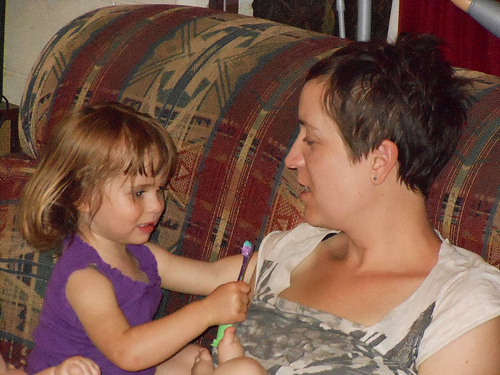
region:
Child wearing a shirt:
[18, 231, 168, 373]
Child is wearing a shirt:
[22, 235, 169, 373]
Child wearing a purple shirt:
[22, 230, 162, 372]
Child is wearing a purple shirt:
[20, 232, 163, 374]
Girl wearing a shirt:
[21, 235, 168, 371]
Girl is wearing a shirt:
[23, 230, 166, 371]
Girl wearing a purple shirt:
[20, 228, 167, 373]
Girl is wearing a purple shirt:
[20, 232, 164, 373]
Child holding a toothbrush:
[207, 239, 258, 363]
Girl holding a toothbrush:
[207, 238, 254, 363]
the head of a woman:
[276, 52, 441, 268]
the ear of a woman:
[339, 130, 424, 180]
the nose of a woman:
[275, 134, 335, 170]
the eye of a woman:
[294, 110, 352, 163]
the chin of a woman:
[288, 177, 355, 237]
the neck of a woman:
[295, 191, 434, 315]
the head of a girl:
[56, 108, 205, 261]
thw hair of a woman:
[284, 42, 464, 179]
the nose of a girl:
[146, 180, 198, 220]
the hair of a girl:
[18, 79, 212, 239]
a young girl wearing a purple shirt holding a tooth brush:
[16, 73, 268, 373]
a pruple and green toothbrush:
[208, 235, 271, 363]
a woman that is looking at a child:
[193, 36, 490, 373]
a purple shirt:
[36, 242, 152, 372]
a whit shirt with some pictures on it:
[240, 232, 499, 373]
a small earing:
[370, 173, 378, 185]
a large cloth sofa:
[1, 2, 499, 369]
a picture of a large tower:
[377, 297, 443, 374]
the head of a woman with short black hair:
[284, 32, 473, 237]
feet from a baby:
[186, 324, 266, 374]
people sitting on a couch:
[94, 41, 493, 339]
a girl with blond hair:
[53, 108, 272, 367]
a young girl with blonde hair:
[66, 100, 251, 305]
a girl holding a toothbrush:
[74, 103, 324, 374]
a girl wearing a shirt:
[14, 116, 214, 347]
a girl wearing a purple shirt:
[21, 80, 174, 322]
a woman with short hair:
[219, 23, 481, 330]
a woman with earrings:
[221, 57, 496, 316]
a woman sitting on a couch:
[209, 38, 429, 365]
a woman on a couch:
[196, 8, 496, 365]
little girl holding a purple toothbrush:
[6, 57, 288, 374]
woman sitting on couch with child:
[12, 17, 489, 365]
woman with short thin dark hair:
[254, 22, 485, 274]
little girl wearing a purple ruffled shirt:
[10, 91, 188, 373]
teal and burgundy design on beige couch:
[173, 55, 257, 187]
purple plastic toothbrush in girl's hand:
[191, 225, 303, 352]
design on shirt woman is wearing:
[276, 311, 353, 370]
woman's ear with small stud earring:
[363, 128, 408, 194]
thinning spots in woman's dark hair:
[322, 60, 388, 133]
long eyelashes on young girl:
[118, 179, 173, 201]